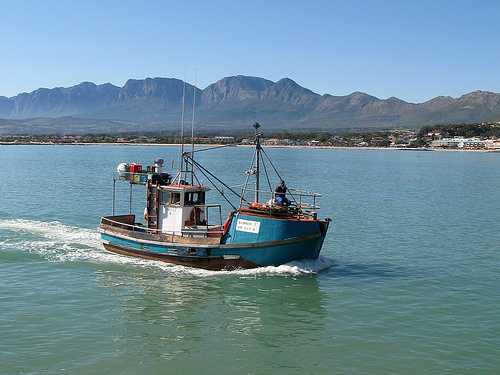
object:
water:
[0, 146, 500, 375]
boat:
[93, 146, 335, 275]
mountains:
[1, 74, 499, 135]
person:
[272, 178, 293, 214]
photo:
[3, 4, 499, 368]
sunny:
[0, 0, 500, 375]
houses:
[268, 130, 499, 151]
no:
[331, 151, 499, 272]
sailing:
[94, 143, 331, 277]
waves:
[1, 215, 104, 261]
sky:
[0, 0, 500, 105]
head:
[279, 180, 285, 187]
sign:
[235, 218, 262, 235]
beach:
[0, 139, 500, 154]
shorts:
[276, 195, 292, 206]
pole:
[189, 61, 198, 185]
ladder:
[144, 179, 161, 235]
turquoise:
[99, 211, 330, 272]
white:
[234, 218, 263, 234]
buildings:
[1, 128, 499, 154]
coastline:
[1, 138, 498, 155]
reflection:
[85, 259, 332, 364]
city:
[1, 128, 499, 153]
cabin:
[146, 184, 210, 238]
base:
[97, 227, 334, 277]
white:
[144, 180, 209, 235]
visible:
[233, 215, 261, 237]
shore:
[0, 127, 500, 155]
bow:
[253, 209, 334, 272]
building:
[428, 132, 484, 150]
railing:
[237, 185, 324, 219]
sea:
[0, 145, 500, 370]